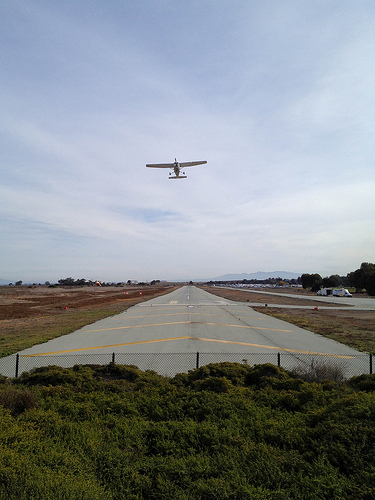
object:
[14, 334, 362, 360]
line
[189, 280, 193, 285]
bush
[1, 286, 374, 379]
runway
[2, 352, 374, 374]
fence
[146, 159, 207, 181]
airplane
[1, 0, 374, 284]
sky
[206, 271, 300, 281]
hill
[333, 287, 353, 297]
truck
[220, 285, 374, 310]
runway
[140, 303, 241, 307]
line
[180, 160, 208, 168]
wing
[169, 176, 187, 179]
tail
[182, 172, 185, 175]
wheel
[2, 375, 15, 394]
leaf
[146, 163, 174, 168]
wing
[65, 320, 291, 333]
paint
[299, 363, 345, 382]
tree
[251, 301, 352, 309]
road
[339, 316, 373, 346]
grass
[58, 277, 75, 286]
tree